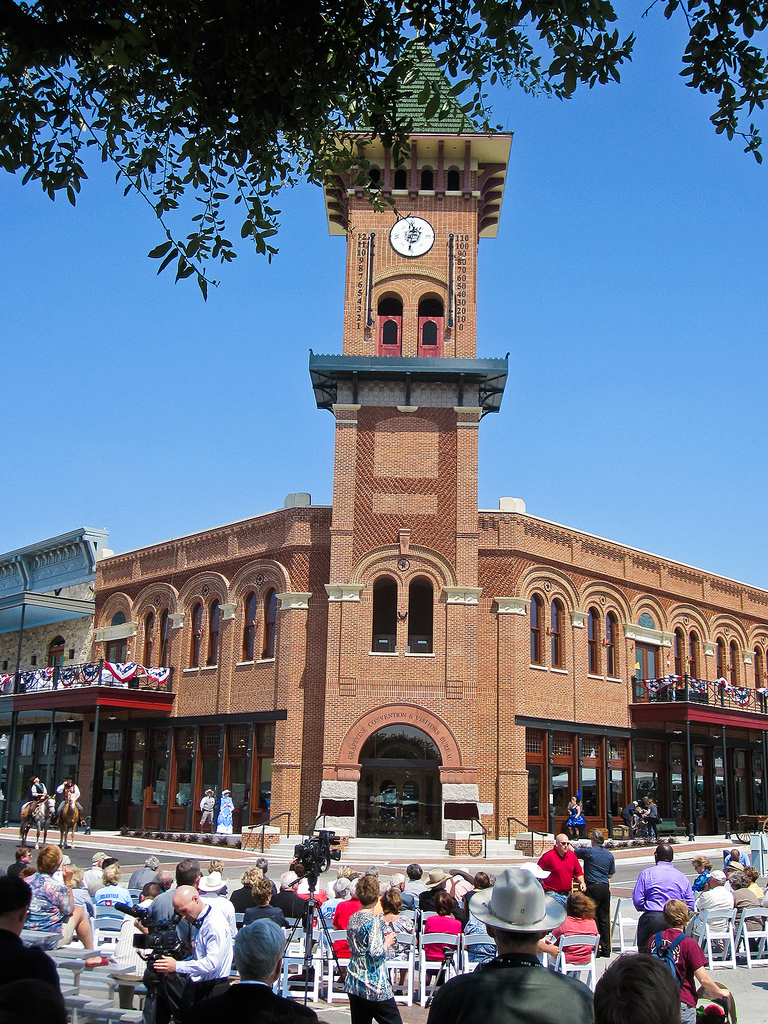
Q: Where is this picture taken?
A: In front of a large building.